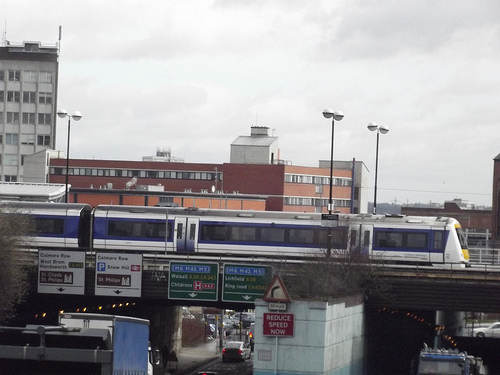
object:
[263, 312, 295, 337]
sign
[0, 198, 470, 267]
train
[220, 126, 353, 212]
building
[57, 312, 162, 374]
van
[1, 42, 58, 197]
building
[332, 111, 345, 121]
lights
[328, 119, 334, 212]
post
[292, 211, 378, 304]
trees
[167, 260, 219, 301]
sign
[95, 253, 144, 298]
sign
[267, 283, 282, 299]
curve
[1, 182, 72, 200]
station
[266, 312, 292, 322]
reduce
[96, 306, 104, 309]
lights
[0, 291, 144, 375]
tunnel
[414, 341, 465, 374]
truck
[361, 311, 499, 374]
tunnel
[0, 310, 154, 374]
traffic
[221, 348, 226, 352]
lights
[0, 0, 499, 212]
sky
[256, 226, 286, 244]
window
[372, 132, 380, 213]
posts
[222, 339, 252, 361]
car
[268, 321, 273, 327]
text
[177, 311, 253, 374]
freeway